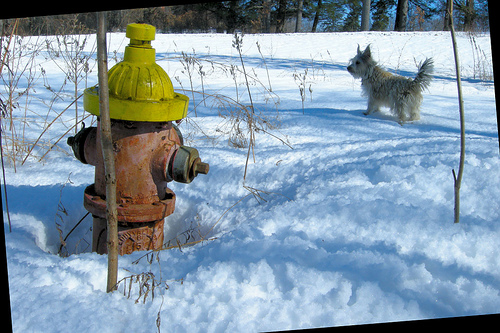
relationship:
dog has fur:
[346, 42, 437, 126] [367, 65, 407, 97]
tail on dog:
[411, 55, 435, 94] [349, 45, 469, 135]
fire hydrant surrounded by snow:
[66, 23, 209, 254] [1, 31, 498, 330]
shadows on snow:
[3, 45, 492, 314] [1, 31, 498, 330]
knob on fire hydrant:
[169, 145, 213, 186] [66, 23, 209, 254]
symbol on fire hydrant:
[113, 225, 159, 255] [66, 20, 211, 252]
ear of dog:
[362, 43, 371, 55] [346, 45, 430, 125]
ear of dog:
[355, 43, 361, 54] [346, 45, 430, 125]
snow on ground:
[1, 31, 498, 330] [245, 126, 461, 321]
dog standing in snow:
[346, 45, 430, 125] [282, 129, 424, 309]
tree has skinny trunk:
[94, 8, 119, 293] [85, 9, 132, 311]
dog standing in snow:
[346, 45, 430, 125] [1, 31, 498, 330]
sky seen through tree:
[222, 0, 484, 30] [291, 0, 310, 30]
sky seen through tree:
[222, 0, 484, 30] [357, 1, 373, 30]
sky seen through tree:
[222, 0, 484, 30] [370, 0, 390, 30]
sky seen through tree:
[222, 0, 484, 30] [340, 0, 363, 30]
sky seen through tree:
[222, 0, 484, 30] [320, 0, 347, 30]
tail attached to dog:
[411, 55, 439, 89] [346, 42, 437, 126]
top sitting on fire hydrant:
[82, 19, 191, 123] [66, 23, 209, 254]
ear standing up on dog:
[363, 43, 371, 55] [344, 40, 434, 126]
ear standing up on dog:
[354, 42, 362, 55] [344, 40, 434, 126]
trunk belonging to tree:
[444, 0, 466, 222] [440, 1, 466, 224]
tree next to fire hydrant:
[94, 8, 119, 293] [66, 20, 211, 252]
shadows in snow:
[0, 51, 500, 315] [314, 141, 478, 252]